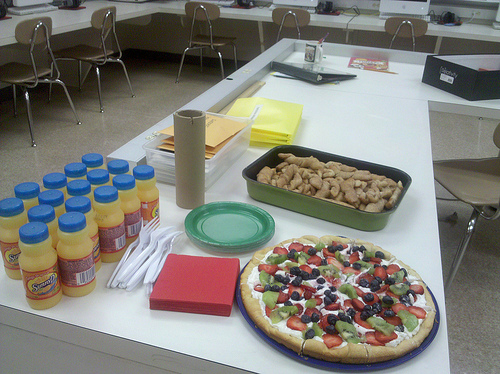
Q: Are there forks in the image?
A: Yes, there is a fork.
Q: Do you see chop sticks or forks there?
A: Yes, there is a fork.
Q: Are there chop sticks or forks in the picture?
A: Yes, there is a fork.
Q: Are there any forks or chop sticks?
A: Yes, there is a fork.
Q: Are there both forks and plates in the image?
A: Yes, there are both a fork and a plate.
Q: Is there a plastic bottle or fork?
A: Yes, there is a plastic fork.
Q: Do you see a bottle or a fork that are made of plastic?
A: Yes, the fork is made of plastic.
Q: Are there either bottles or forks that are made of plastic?
A: Yes, the fork is made of plastic.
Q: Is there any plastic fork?
A: Yes, there is a fork that is made of plastic.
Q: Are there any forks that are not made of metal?
A: Yes, there is a fork that is made of plastic.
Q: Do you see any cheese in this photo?
A: No, there is no cheese.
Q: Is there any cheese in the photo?
A: No, there is no cheese.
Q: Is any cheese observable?
A: No, there is no cheese.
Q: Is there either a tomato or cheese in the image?
A: No, there are no cheese or tomatoes.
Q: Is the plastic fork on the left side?
A: Yes, the fork is on the left of the image.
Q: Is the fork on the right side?
A: No, the fork is on the left of the image.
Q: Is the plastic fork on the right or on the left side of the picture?
A: The fork is on the left of the image.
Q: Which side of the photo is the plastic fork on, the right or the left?
A: The fork is on the left of the image.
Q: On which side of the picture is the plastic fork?
A: The fork is on the left of the image.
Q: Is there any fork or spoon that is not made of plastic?
A: No, there is a fork but it is made of plastic.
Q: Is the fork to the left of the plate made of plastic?
A: Yes, the fork is made of plastic.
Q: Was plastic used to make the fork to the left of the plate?
A: Yes, the fork is made of plastic.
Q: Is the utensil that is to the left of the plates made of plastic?
A: Yes, the fork is made of plastic.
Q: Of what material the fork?
A: The fork is made of plastic.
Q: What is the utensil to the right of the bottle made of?
A: The fork is made of plastic.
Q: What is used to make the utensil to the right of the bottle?
A: The fork is made of plastic.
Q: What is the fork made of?
A: The fork is made of plastic.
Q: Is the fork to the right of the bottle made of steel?
A: No, the fork is made of plastic.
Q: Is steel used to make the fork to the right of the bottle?
A: No, the fork is made of plastic.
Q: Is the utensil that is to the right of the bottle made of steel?
A: No, the fork is made of plastic.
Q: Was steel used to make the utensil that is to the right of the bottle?
A: No, the fork is made of plastic.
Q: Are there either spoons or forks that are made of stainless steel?
A: No, there is a fork but it is made of plastic.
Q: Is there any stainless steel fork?
A: No, there is a fork but it is made of plastic.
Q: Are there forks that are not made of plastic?
A: No, there is a fork but it is made of plastic.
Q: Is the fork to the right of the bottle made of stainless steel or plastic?
A: The fork is made of plastic.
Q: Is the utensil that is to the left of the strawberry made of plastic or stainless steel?
A: The fork is made of plastic.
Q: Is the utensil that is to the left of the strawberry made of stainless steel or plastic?
A: The fork is made of plastic.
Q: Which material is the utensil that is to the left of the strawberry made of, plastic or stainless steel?
A: The fork is made of plastic.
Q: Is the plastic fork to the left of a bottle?
A: No, the fork is to the right of a bottle.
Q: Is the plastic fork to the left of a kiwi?
A: Yes, the fork is to the left of a kiwi.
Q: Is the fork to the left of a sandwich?
A: No, the fork is to the left of a kiwi.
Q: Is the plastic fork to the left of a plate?
A: Yes, the fork is to the left of a plate.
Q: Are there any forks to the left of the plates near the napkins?
A: Yes, there is a fork to the left of the plates.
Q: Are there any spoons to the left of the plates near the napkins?
A: No, there is a fork to the left of the plates.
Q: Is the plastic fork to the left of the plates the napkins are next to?
A: Yes, the fork is to the left of the plates.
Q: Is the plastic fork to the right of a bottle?
A: Yes, the fork is to the right of a bottle.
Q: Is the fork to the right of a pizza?
A: No, the fork is to the right of a bottle.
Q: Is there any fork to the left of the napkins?
A: Yes, there is a fork to the left of the napkins.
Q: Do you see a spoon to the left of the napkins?
A: No, there is a fork to the left of the napkins.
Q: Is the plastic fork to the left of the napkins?
A: Yes, the fork is to the left of the napkins.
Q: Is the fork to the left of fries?
A: No, the fork is to the left of the napkins.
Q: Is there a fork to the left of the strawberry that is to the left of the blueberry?
A: Yes, there is a fork to the left of the strawberry.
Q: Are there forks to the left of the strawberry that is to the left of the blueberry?
A: Yes, there is a fork to the left of the strawberry.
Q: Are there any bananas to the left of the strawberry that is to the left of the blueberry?
A: No, there is a fork to the left of the strawberry.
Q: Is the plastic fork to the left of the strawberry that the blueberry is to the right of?
A: Yes, the fork is to the left of the strawberry.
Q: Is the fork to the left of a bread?
A: No, the fork is to the left of the strawberry.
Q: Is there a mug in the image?
A: Yes, there is a mug.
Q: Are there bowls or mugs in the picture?
A: Yes, there is a mug.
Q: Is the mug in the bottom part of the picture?
A: No, the mug is in the top of the image.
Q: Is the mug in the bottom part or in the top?
A: The mug is in the top of the image.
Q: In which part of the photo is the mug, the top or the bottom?
A: The mug is in the top of the image.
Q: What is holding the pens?
A: The mug is holding the pens.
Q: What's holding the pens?
A: The mug is holding the pens.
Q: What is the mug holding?
A: The mug is holding the pens.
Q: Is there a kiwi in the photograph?
A: Yes, there is a kiwi.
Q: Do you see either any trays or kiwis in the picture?
A: Yes, there is a kiwi.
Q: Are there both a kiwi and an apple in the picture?
A: No, there is a kiwi but no apples.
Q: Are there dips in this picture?
A: No, there are no dips.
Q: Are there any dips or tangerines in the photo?
A: No, there are no dips or tangerines.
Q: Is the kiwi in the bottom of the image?
A: Yes, the kiwi is in the bottom of the image.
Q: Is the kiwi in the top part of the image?
A: No, the kiwi is in the bottom of the image.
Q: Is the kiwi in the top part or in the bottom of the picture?
A: The kiwi is in the bottom of the image.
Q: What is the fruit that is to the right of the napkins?
A: The fruit is a kiwi.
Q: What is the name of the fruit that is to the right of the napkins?
A: The fruit is a kiwi.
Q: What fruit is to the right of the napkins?
A: The fruit is a kiwi.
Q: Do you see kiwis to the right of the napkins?
A: Yes, there is a kiwi to the right of the napkins.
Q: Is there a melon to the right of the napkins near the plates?
A: No, there is a kiwi to the right of the napkins.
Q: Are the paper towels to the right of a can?
A: No, the paper towels are to the right of a bottle.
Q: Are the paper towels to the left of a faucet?
A: No, the paper towels are to the left of a binder.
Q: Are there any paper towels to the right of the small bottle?
A: Yes, there are paper towels to the right of the bottle.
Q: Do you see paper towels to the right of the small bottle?
A: Yes, there are paper towels to the right of the bottle.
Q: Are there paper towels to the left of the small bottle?
A: No, the paper towels are to the right of the bottle.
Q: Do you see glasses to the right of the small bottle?
A: No, there are paper towels to the right of the bottle.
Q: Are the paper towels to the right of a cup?
A: No, the paper towels are to the right of the bottle.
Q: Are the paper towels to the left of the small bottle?
A: No, the paper towels are to the right of the bottle.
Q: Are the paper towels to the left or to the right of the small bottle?
A: The paper towels are to the right of the bottle.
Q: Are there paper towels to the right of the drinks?
A: Yes, there are paper towels to the right of the drinks.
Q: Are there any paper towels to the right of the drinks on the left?
A: Yes, there are paper towels to the right of the drinks.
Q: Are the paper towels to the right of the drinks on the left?
A: Yes, the paper towels are to the right of the drinks.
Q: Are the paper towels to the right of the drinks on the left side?
A: Yes, the paper towels are to the right of the drinks.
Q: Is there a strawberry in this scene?
A: Yes, there are strawberries.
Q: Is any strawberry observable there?
A: Yes, there are strawberries.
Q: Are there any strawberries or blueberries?
A: Yes, there are strawberries.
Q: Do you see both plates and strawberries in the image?
A: Yes, there are both strawberries and a plate.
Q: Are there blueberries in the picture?
A: Yes, there are blueberries.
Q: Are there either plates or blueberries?
A: Yes, there are blueberries.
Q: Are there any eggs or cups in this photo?
A: No, there are no cups or eggs.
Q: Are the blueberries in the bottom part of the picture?
A: Yes, the blueberries are in the bottom of the image.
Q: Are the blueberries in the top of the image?
A: No, the blueberries are in the bottom of the image.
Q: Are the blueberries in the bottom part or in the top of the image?
A: The blueberries are in the bottom of the image.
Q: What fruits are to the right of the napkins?
A: The fruits are blueberries.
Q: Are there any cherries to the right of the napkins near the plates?
A: No, there are blueberries to the right of the napkins.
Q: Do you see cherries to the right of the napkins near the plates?
A: No, there are blueberries to the right of the napkins.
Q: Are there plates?
A: Yes, there is a plate.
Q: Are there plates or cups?
A: Yes, there is a plate.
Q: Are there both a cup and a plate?
A: No, there is a plate but no cups.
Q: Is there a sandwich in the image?
A: No, there are no sandwiches.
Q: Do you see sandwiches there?
A: No, there are no sandwiches.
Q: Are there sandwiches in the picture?
A: No, there are no sandwiches.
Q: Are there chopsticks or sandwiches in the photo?
A: No, there are no sandwiches or chopsticks.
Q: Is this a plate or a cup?
A: This is a plate.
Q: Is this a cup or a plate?
A: This is a plate.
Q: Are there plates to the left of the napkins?
A: No, the plate is to the right of the napkins.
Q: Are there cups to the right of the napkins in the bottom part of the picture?
A: No, there is a plate to the right of the napkins.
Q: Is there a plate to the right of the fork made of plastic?
A: Yes, there is a plate to the right of the fork.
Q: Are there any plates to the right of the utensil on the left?
A: Yes, there is a plate to the right of the fork.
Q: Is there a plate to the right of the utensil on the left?
A: Yes, there is a plate to the right of the fork.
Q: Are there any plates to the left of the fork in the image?
A: No, the plate is to the right of the fork.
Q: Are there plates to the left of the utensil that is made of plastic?
A: No, the plate is to the right of the fork.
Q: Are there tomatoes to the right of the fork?
A: No, there is a plate to the right of the fork.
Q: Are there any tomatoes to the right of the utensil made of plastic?
A: No, there is a plate to the right of the fork.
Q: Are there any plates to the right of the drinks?
A: Yes, there is a plate to the right of the drinks.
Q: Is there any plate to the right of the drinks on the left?
A: Yes, there is a plate to the right of the drinks.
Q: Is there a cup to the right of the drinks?
A: No, there is a plate to the right of the drinks.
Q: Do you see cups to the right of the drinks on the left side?
A: No, there is a plate to the right of the drinks.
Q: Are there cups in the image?
A: No, there are no cups.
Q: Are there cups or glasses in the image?
A: No, there are no cups or glasses.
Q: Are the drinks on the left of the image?
A: Yes, the drinks are on the left of the image.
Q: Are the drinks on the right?
A: No, the drinks are on the left of the image.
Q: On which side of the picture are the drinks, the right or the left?
A: The drinks are on the left of the image.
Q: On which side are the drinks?
A: The drinks are on the left of the image.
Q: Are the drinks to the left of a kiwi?
A: Yes, the drinks are to the left of a kiwi.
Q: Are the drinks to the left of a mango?
A: No, the drinks are to the left of a kiwi.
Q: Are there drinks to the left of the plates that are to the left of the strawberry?
A: Yes, there are drinks to the left of the plates.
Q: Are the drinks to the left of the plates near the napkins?
A: Yes, the drinks are to the left of the plates.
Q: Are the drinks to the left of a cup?
A: No, the drinks are to the left of the plate.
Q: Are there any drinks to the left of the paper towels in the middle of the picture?
A: Yes, there are drinks to the left of the paper towels.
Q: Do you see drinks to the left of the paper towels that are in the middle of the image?
A: Yes, there are drinks to the left of the paper towels.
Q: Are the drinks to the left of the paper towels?
A: Yes, the drinks are to the left of the paper towels.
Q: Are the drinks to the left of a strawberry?
A: Yes, the drinks are to the left of a strawberry.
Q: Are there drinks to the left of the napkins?
A: Yes, there are drinks to the left of the napkins.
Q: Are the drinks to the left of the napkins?
A: Yes, the drinks are to the left of the napkins.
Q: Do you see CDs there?
A: No, there are no cds.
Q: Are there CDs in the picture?
A: No, there are no cds.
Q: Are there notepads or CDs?
A: No, there are no CDs or notepads.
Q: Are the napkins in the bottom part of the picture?
A: Yes, the napkins are in the bottom of the image.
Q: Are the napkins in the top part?
A: No, the napkins are in the bottom of the image.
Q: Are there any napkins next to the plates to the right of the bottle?
A: Yes, there are napkins next to the plates.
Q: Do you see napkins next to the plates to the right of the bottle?
A: Yes, there are napkins next to the plates.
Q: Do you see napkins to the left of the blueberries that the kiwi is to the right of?
A: Yes, there are napkins to the left of the blueberries.